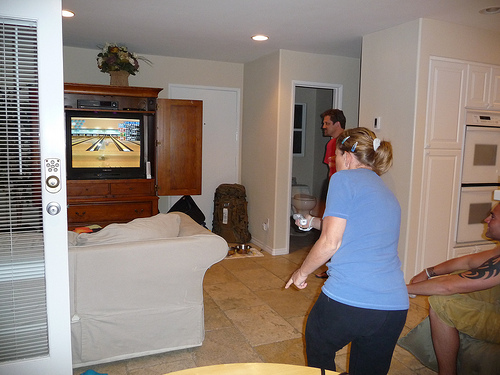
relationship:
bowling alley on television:
[66, 115, 143, 172] [54, 107, 155, 189]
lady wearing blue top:
[282, 126, 410, 375] [321, 167, 411, 311]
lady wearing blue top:
[282, 126, 410, 375] [336, 169, 413, 284]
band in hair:
[371, 135, 381, 150] [329, 122, 398, 182]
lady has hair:
[282, 126, 410, 375] [329, 122, 398, 182]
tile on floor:
[76, 247, 341, 374] [74, 247, 436, 373]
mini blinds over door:
[2, 15, 45, 359] [1, 1, 78, 373]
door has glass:
[1, 1, 78, 373] [1, 17, 52, 360]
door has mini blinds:
[1, 1, 78, 373] [2, 15, 45, 359]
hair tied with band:
[338, 131, 397, 173] [366, 134, 385, 155]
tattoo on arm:
[457, 253, 499, 285] [404, 250, 484, 300]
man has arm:
[403, 199, 484, 373] [404, 250, 484, 300]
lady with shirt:
[281, 124, 417, 374] [326, 166, 406, 301]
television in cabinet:
[61, 77, 204, 212] [4, 72, 214, 236]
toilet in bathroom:
[292, 184, 314, 228] [286, 73, 340, 248]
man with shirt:
[314, 107, 351, 281] [323, 132, 347, 175]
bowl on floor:
[234, 242, 252, 258] [205, 258, 307, 358]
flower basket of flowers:
[90, 43, 141, 89] [95, 41, 143, 69]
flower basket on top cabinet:
[90, 43, 141, 89] [68, 83, 205, 225]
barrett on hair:
[340, 133, 352, 146] [337, 127, 392, 174]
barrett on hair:
[350, 139, 360, 151] [337, 127, 392, 174]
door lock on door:
[44, 157, 62, 194] [1, 1, 78, 373]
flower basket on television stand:
[97, 35, 149, 90] [59, 73, 194, 233]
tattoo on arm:
[457, 252, 499, 282] [405, 253, 497, 294]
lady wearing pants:
[282, 126, 410, 375] [303, 287, 413, 373]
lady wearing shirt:
[282, 126, 410, 375] [240, 182, 448, 321]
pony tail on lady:
[360, 134, 395, 174] [282, 126, 410, 375]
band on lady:
[371, 135, 381, 150] [282, 126, 410, 375]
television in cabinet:
[64, 104, 155, 181] [62, 81, 220, 220]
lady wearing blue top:
[281, 124, 417, 374] [321, 167, 411, 311]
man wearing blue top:
[314, 105, 350, 280] [321, 167, 411, 311]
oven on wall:
[459, 110, 499, 189] [422, 25, 462, 138]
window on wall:
[290, 102, 307, 159] [361, 17, 421, 296]